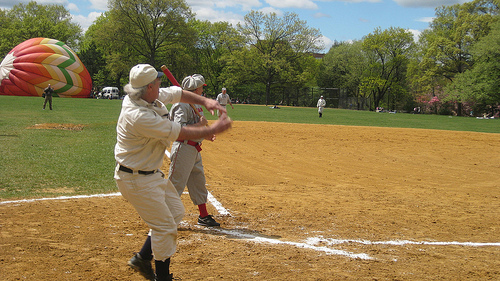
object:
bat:
[158, 64, 217, 142]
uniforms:
[164, 103, 223, 206]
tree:
[397, 0, 500, 117]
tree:
[211, 10, 325, 105]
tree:
[76, 0, 248, 96]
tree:
[318, 24, 421, 104]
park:
[0, 0, 500, 281]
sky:
[6, 0, 444, 53]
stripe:
[57, 40, 73, 100]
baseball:
[157, 55, 232, 237]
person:
[316, 95, 326, 117]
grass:
[1, 93, 499, 206]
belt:
[117, 165, 161, 176]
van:
[95, 85, 118, 97]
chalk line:
[206, 186, 500, 264]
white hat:
[122, 63, 161, 91]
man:
[112, 63, 231, 281]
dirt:
[236, 124, 490, 274]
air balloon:
[1, 37, 93, 99]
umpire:
[107, 57, 183, 261]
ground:
[1, 92, 498, 279]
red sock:
[197, 203, 209, 217]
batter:
[154, 73, 220, 228]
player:
[42, 83, 57, 110]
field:
[0, 88, 496, 280]